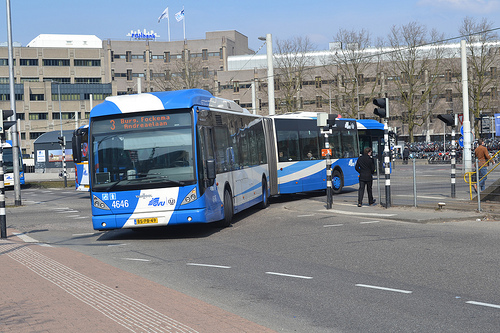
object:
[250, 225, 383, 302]
section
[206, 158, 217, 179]
mirror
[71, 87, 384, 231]
bus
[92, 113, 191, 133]
screen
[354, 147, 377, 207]
man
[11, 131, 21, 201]
section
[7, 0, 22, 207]
pole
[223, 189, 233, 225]
wheel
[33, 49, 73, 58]
section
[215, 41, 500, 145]
building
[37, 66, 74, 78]
part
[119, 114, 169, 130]
destination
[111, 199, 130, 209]
number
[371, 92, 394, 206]
standing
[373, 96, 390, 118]
light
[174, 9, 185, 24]
flags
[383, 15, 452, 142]
zero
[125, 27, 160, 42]
sign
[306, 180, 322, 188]
blue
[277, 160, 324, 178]
striped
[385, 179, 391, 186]
white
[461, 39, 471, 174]
poles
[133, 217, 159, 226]
numberplate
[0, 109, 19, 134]
traffic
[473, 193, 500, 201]
steps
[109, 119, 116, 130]
number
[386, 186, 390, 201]
black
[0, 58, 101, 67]
lots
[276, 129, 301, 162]
windows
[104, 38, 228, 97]
front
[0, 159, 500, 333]
road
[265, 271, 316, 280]
stripes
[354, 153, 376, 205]
suit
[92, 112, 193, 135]
digital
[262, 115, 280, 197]
flexible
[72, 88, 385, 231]
turn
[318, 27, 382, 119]
tree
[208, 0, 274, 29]
patch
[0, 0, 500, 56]
sky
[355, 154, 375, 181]
clothes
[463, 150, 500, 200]
railing